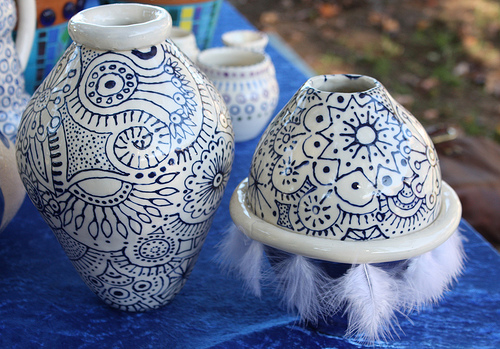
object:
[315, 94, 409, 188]
star shape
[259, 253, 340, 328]
feather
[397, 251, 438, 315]
feather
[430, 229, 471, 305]
feather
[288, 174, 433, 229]
whitering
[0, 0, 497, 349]
tablecloth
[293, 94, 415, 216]
star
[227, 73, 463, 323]
vase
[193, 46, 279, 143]
vase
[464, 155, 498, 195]
ground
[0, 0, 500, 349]
table surface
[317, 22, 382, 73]
ground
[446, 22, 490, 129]
background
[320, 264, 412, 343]
feathers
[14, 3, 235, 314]
vase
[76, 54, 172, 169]
swirl pattern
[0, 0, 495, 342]
table cloth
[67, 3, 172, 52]
pot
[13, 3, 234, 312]
ceramic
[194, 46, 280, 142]
ceramic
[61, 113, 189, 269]
designs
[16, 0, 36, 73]
handle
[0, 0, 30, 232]
vase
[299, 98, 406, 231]
designs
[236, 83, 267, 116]
designs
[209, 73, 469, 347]
item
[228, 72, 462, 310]
ceramic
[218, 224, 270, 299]
feathers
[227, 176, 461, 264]
ring